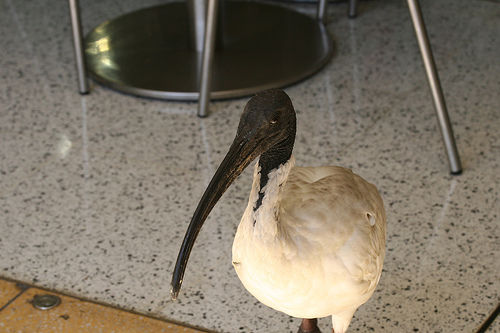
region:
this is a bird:
[159, 75, 427, 303]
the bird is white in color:
[266, 245, 358, 297]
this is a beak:
[155, 106, 225, 306]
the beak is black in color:
[198, 182, 228, 211]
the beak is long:
[166, 190, 209, 319]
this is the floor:
[345, 56, 450, 180]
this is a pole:
[406, 20, 481, 146]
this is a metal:
[409, 10, 471, 104]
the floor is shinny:
[17, 120, 160, 228]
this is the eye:
[266, 109, 283, 125]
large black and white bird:
[167, 84, 397, 331]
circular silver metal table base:
[79, 0, 337, 105]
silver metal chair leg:
[401, 0, 466, 180]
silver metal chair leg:
[66, 0, 93, 97]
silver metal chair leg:
[195, 0, 219, 122]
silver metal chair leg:
[311, 1, 332, 23]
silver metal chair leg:
[343, 0, 360, 22]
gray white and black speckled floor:
[0, 0, 499, 332]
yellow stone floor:
[0, 269, 257, 331]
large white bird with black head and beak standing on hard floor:
[168, 83, 395, 331]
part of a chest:
[262, 264, 323, 323]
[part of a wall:
[409, 269, 435, 308]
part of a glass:
[406, 225, 441, 280]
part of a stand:
[415, 115, 477, 175]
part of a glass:
[113, 187, 160, 231]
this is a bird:
[171, 75, 409, 326]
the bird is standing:
[170, 75, 390, 332]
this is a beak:
[156, 132, 236, 297]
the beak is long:
[163, 149, 236, 300]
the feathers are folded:
[292, 169, 369, 303]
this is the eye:
[268, 113, 283, 124]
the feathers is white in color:
[283, 167, 376, 297]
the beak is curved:
[160, 155, 241, 299]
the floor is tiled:
[46, 125, 159, 252]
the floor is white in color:
[38, 131, 140, 250]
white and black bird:
[152, 97, 399, 331]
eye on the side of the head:
[269, 111, 281, 128]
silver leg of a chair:
[408, 10, 472, 174]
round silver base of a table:
[79, 4, 349, 107]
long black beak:
[152, 150, 242, 306]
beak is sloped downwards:
[164, 134, 254, 312]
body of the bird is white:
[236, 160, 386, 328]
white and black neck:
[249, 161, 281, 229]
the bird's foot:
[282, 316, 322, 331]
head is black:
[239, 90, 304, 168]